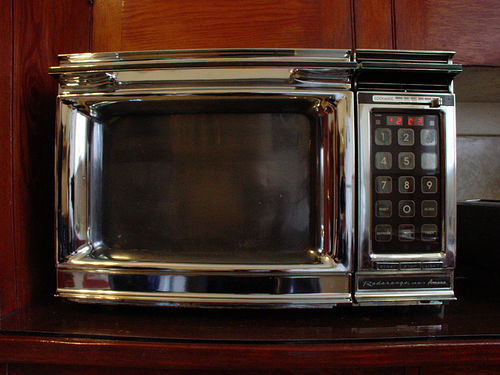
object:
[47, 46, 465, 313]
microwave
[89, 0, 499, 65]
cabinets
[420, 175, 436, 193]
buttons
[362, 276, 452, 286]
words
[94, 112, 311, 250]
window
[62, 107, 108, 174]
reflection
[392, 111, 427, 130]
numbers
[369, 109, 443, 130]
display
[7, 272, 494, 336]
glass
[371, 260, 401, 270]
buttons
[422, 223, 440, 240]
word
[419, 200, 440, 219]
button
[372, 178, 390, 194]
word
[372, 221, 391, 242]
button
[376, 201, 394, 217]
key pad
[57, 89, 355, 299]
door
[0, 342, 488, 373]
shelf